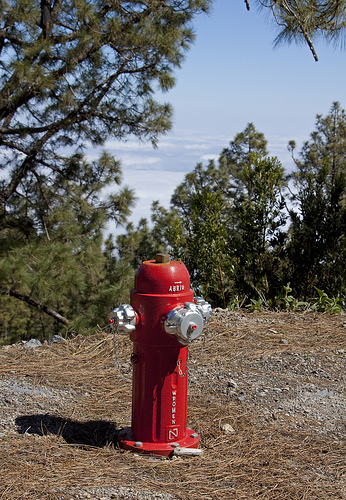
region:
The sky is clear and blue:
[201, 14, 300, 126]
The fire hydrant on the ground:
[98, 235, 223, 465]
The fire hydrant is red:
[123, 261, 177, 448]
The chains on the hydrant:
[110, 334, 207, 376]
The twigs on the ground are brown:
[22, 447, 330, 498]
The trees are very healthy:
[195, 154, 344, 300]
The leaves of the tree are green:
[200, 176, 326, 283]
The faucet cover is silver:
[162, 301, 207, 347]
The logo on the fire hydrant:
[165, 387, 182, 441]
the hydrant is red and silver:
[102, 220, 228, 468]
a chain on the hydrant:
[152, 327, 209, 392]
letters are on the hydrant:
[160, 385, 182, 439]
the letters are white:
[167, 384, 185, 433]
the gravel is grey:
[242, 333, 338, 434]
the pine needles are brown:
[191, 394, 309, 491]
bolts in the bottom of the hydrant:
[170, 432, 199, 452]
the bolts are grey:
[159, 423, 203, 455]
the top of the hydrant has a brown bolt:
[142, 241, 177, 268]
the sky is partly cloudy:
[73, 73, 299, 218]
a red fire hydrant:
[106, 250, 218, 461]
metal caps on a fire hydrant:
[100, 290, 216, 346]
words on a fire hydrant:
[167, 385, 181, 430]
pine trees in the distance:
[4, 123, 130, 334]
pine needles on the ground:
[42, 436, 301, 499]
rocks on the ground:
[245, 364, 345, 427]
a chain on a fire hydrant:
[170, 322, 223, 375]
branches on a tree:
[59, 155, 134, 218]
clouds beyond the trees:
[99, 130, 214, 207]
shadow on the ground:
[21, 391, 106, 453]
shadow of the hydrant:
[31, 392, 93, 461]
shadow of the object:
[13, 395, 103, 460]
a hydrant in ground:
[99, 258, 227, 468]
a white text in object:
[163, 382, 190, 445]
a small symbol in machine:
[166, 422, 191, 443]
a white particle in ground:
[208, 411, 239, 437]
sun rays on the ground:
[211, 367, 315, 495]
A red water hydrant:
[100, 242, 223, 467]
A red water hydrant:
[99, 250, 224, 462]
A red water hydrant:
[103, 251, 216, 463]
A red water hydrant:
[101, 248, 220, 465]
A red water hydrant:
[100, 246, 214, 463]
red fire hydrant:
[101, 242, 213, 462]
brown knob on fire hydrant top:
[147, 250, 174, 264]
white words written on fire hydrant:
[161, 382, 186, 448]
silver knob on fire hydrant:
[165, 301, 207, 346]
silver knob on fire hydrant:
[192, 286, 217, 327]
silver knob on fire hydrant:
[105, 302, 138, 335]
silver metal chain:
[109, 318, 133, 378]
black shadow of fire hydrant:
[10, 404, 141, 452]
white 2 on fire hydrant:
[165, 420, 182, 440]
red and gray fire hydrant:
[117, 225, 218, 440]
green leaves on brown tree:
[191, 181, 228, 216]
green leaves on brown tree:
[267, 261, 299, 300]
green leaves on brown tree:
[300, 203, 332, 247]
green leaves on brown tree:
[40, 254, 74, 297]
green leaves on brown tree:
[22, 270, 67, 308]